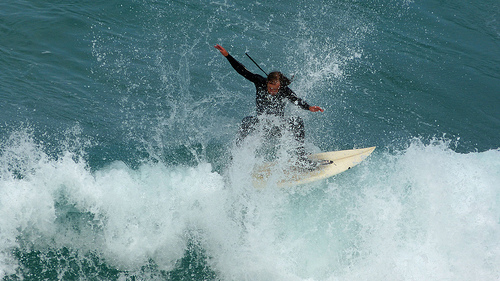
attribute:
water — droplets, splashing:
[36, 79, 196, 193]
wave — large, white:
[77, 167, 203, 242]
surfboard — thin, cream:
[282, 149, 410, 197]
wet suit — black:
[206, 48, 317, 148]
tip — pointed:
[339, 132, 383, 176]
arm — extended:
[202, 33, 251, 84]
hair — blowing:
[248, 56, 310, 110]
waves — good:
[124, 151, 194, 231]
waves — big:
[92, 136, 201, 257]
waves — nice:
[116, 160, 203, 250]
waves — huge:
[70, 149, 201, 272]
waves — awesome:
[90, 176, 239, 263]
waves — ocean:
[143, 141, 225, 241]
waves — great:
[63, 122, 239, 258]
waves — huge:
[84, 158, 182, 266]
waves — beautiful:
[104, 184, 205, 260]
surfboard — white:
[238, 151, 365, 191]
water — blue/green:
[46, 130, 160, 240]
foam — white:
[4, 130, 494, 279]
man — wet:
[211, 43, 321, 168]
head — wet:
[263, 72, 290, 96]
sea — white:
[1, 4, 496, 277]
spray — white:
[4, 13, 497, 278]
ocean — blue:
[7, 9, 492, 279]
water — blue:
[0, 3, 493, 278]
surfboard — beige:
[249, 139, 379, 185]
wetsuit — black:
[225, 55, 307, 156]